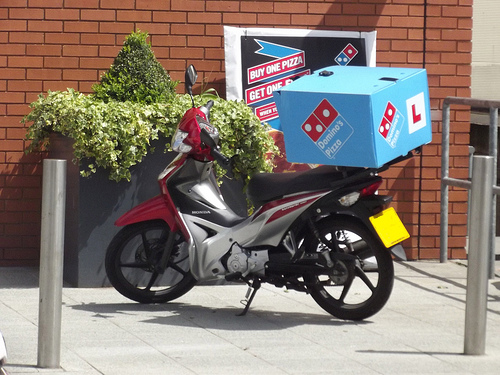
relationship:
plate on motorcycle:
[366, 201, 409, 255] [101, 55, 436, 331]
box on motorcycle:
[279, 60, 438, 165] [101, 129, 386, 312]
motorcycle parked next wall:
[90, 106, 420, 309] [3, 3, 473, 264]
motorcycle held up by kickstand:
[104, 63, 413, 322] [237, 282, 257, 307]